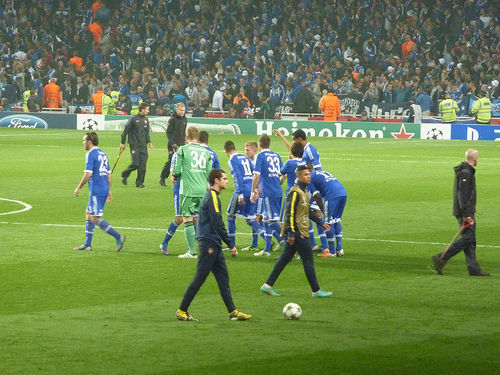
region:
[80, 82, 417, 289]
Players in the field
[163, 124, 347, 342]
Soccer ball on the field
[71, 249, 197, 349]
Green turf on the field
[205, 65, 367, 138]
Spectators watching the game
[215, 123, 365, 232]
Players wearing blue uniforms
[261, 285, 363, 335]
Soccer ball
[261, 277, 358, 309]
Green Nike shoes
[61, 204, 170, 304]
Blue socks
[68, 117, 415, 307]
Players finishing up a game of soccer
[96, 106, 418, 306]
People on the soccer field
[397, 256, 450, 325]
part of a green field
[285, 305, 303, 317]
a white round football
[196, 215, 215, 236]
part of a dark jacket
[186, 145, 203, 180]
part of a green jersey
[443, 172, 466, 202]
part of a black jumper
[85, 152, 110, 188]
part of a blue jersey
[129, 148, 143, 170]
part of a black track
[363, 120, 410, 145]
part of a banner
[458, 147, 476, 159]
part of a bald head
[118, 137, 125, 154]
part of a right hand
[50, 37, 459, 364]
People playing soccer.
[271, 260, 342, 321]
Soccer ball on the field.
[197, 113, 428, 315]
People in blue uniforms.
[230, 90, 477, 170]
Green sign behind the field.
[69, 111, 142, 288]
Man walking on the field.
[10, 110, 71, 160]
Ford sign in the background.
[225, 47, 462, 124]
Crowds in the stands.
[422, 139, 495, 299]
Man in a black hoodie.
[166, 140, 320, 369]
Man in a black and yellow outfit.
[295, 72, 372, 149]
Person in an orange suit.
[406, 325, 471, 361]
part of a green grass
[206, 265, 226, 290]
part of a dark track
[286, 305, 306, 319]
a round white football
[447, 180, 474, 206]
part of a black jacket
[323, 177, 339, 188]
part of a blue jersey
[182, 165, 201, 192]
part of a green jersey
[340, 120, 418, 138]
part of a banner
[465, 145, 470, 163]
part of a bald head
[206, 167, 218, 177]
hair of the man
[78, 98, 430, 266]
soccer players on field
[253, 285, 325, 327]
soccer ball on field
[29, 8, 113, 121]
men wearing orange jackets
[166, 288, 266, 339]
man wearing yellow tennis shoes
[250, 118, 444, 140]
advertising banner on wall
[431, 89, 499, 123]
men wearing yellow safety jackets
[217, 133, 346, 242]
soccer team wearing blue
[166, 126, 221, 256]
soccer player wearing green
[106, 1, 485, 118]
crowd watching soccer game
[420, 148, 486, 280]
man carrying pitchfork